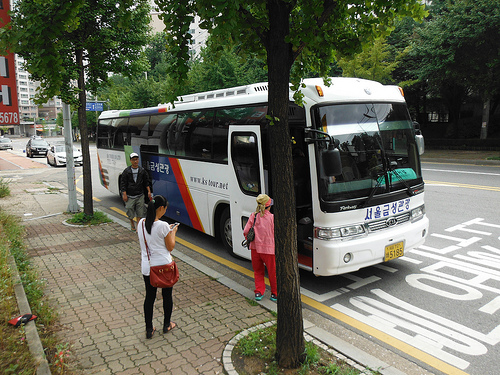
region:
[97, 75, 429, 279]
a bus parked on a street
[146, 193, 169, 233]
a woman with long black hair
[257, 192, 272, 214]
a woman with blonde hair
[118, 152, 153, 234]
man walking on a sidewalk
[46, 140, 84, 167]
a white car on the street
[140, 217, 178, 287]
woman carrying a red purse on her shoulder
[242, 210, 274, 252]
woman wearing a pink shirt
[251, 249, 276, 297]
woman wearing red pants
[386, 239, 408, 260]
a yellow license plate on the front of a bus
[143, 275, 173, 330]
woman wearing black leggings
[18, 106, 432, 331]
people boarding the bus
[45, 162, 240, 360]
people on the sidewalk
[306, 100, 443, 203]
front of the bus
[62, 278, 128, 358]
the ground is brick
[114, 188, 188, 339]
back of the woman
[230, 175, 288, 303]
back of the woman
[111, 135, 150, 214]
the man is walking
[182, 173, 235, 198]
text on the bus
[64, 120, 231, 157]
window of the bus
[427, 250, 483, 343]
text on the road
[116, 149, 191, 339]
the people on the sidewalk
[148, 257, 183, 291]
the bag on the waist of the women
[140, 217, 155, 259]
the strap on the womens back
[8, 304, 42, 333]
the book on the step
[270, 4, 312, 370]
the trunk of the tree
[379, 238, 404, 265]
the yellow liscense plate on the bus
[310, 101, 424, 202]
the front windshield on the bus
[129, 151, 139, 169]
the white hat on the man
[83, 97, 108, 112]
the blue sign on the street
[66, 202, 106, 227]
the grass at the base of the tree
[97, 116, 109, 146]
glass window on buss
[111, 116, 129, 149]
glass window on buss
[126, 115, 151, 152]
glass window on buss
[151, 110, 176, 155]
glass window on buss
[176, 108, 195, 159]
glass window on buss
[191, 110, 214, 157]
glass window on buss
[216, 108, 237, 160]
glass window on buss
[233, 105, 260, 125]
glass window on buss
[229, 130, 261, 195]
glass window on buss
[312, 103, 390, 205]
glass window on buss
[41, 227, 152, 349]
The ground is made of concrete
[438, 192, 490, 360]
The street is made of asphalt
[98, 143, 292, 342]
The people on the side of the bus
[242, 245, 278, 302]
The woman is wearing red pants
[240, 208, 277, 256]
The woman is wearing a pink shirt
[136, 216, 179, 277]
The woman is wearing a white shirt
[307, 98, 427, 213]
The windshield of the bus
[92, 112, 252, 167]
The side windows of the bus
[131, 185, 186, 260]
The woman is on her cell phone